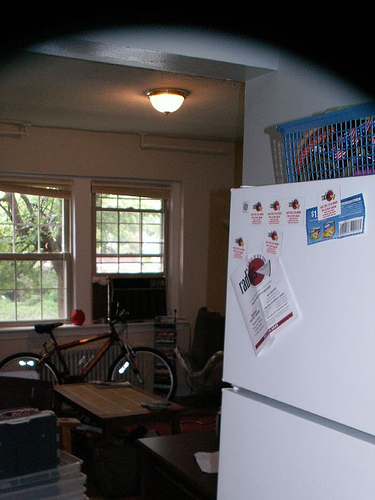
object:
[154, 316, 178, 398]
cd stand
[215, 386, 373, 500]
door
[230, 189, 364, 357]
magnets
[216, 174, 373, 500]
refrigerator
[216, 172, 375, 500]
freezer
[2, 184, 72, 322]
window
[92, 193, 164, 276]
window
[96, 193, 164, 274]
outside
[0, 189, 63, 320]
outside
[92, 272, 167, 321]
conditioner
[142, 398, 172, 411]
remotes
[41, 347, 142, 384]
radiator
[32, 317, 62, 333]
seat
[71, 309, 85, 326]
vase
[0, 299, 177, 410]
bicycle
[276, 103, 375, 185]
laundry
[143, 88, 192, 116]
light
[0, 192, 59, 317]
trees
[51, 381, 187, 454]
table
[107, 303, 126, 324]
handles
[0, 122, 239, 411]
wall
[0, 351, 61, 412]
wheel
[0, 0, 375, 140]
ceiling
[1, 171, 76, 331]
window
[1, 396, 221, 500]
floor